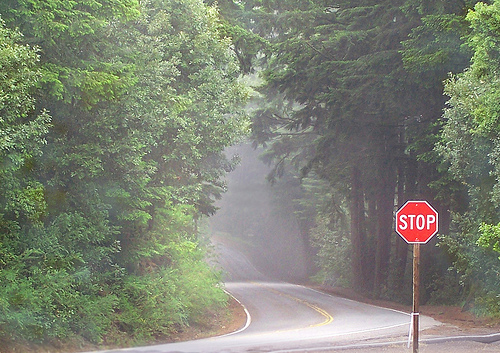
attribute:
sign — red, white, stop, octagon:
[392, 197, 441, 244]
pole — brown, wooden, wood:
[406, 241, 426, 352]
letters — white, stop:
[397, 213, 438, 232]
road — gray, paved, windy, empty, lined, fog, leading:
[55, 264, 435, 352]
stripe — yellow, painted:
[275, 285, 336, 323]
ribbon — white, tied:
[406, 311, 418, 347]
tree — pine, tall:
[226, 2, 447, 300]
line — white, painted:
[218, 279, 254, 338]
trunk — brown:
[366, 165, 397, 288]